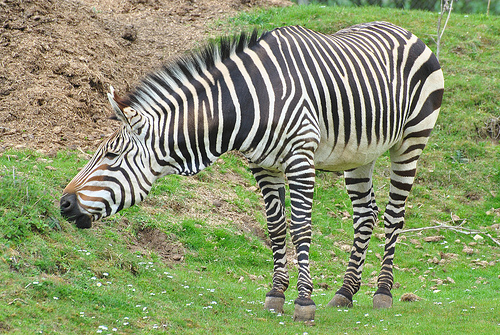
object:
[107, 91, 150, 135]
ears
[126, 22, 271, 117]
mane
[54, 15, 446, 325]
animal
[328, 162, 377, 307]
leg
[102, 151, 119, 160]
eye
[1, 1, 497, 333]
field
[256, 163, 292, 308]
leg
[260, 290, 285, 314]
gray hooves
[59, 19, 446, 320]
striped zebra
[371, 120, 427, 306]
leg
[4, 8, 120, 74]
hill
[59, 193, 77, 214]
nose